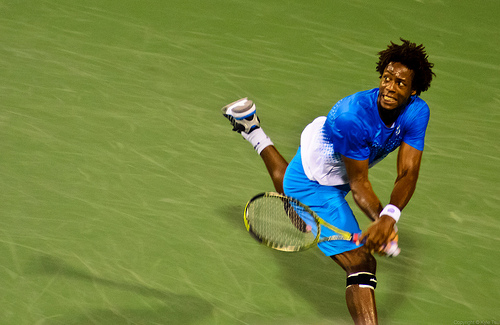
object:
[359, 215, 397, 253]
hands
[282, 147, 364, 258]
shorts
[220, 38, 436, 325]
man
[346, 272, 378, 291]
band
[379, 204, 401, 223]
band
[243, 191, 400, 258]
racket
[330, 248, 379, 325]
leg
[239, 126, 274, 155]
socks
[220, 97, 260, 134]
shoes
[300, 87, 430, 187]
shirt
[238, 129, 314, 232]
leg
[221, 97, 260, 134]
feet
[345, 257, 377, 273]
man's knee